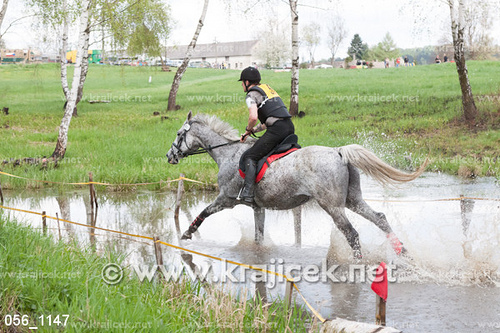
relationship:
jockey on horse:
[237, 59, 296, 152] [156, 110, 413, 264]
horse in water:
[156, 110, 413, 264] [143, 219, 472, 288]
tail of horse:
[345, 134, 426, 192] [156, 110, 413, 264]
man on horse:
[232, 61, 291, 115] [156, 110, 413, 264]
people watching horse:
[389, 53, 447, 69] [156, 110, 413, 264]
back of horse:
[287, 144, 336, 163] [156, 110, 413, 264]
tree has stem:
[41, 4, 100, 160] [59, 27, 72, 55]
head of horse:
[163, 113, 210, 165] [156, 110, 413, 264]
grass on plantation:
[106, 123, 145, 169] [84, 18, 396, 120]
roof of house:
[202, 37, 257, 56] [161, 33, 287, 82]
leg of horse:
[324, 199, 366, 271] [156, 110, 413, 264]